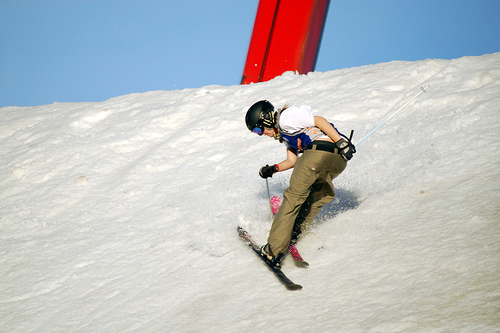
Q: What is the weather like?
A: It is clear.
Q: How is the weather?
A: It is clear.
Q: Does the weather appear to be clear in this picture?
A: Yes, it is clear.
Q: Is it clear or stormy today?
A: It is clear.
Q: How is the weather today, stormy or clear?
A: It is clear.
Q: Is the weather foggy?
A: No, it is clear.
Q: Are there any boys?
A: No, there are no boys.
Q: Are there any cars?
A: No, there are no cars.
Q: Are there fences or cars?
A: No, there are no cars or fences.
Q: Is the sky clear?
A: Yes, the sky is clear.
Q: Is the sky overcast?
A: No, the sky is clear.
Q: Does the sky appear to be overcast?
A: No, the sky is clear.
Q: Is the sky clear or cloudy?
A: The sky is clear.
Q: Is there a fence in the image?
A: No, there are no fences.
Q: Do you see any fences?
A: No, there are no fences.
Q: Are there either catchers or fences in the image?
A: No, there are no fences or catchers.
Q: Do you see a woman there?
A: No, there are no women.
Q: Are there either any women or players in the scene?
A: No, there are no women or players.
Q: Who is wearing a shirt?
A: The man is wearing a shirt.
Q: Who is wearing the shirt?
A: The man is wearing a shirt.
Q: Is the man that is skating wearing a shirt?
A: Yes, the man is wearing a shirt.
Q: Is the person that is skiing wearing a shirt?
A: Yes, the man is wearing a shirt.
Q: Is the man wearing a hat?
A: No, the man is wearing a shirt.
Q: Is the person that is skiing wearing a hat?
A: No, the man is wearing a shirt.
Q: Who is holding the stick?
A: The man is holding the stick.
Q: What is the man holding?
A: The man is holding the stick.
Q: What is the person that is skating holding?
A: The man is holding the stick.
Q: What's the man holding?
A: The man is holding the stick.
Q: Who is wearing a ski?
A: The man is wearing a ski.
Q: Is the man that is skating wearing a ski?
A: Yes, the man is wearing a ski.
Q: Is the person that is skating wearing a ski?
A: Yes, the man is wearing a ski.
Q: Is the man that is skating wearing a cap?
A: No, the man is wearing a ski.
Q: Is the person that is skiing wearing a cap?
A: No, the man is wearing a ski.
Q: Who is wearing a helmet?
A: The man is wearing a helmet.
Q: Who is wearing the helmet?
A: The man is wearing a helmet.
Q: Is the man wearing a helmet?
A: Yes, the man is wearing a helmet.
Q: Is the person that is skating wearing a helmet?
A: Yes, the man is wearing a helmet.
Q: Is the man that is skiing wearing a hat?
A: No, the man is wearing a helmet.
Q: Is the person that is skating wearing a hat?
A: No, the man is wearing a helmet.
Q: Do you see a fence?
A: No, there are no fences.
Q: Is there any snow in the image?
A: Yes, there is snow.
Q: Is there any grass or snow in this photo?
A: Yes, there is snow.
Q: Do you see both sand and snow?
A: No, there is snow but no sand.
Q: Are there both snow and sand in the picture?
A: No, there is snow but no sand.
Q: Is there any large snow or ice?
A: Yes, there is large snow.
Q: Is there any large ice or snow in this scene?
A: Yes, there is large snow.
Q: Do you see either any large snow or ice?
A: Yes, there is large snow.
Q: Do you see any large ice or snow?
A: Yes, there is large snow.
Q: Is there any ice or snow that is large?
A: Yes, the snow is large.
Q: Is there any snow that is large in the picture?
A: Yes, there is large snow.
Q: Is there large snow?
A: Yes, there is large snow.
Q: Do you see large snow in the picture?
A: Yes, there is large snow.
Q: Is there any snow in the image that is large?
A: Yes, there is snow that is large.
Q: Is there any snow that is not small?
A: Yes, there is large snow.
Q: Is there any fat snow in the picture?
A: Yes, there is fat snow.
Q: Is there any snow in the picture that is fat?
A: Yes, there is snow that is fat.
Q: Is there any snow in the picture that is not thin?
A: Yes, there is fat snow.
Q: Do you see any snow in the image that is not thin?
A: Yes, there is fat snow.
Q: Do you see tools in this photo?
A: No, there are no tools.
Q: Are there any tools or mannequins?
A: No, there are no tools or mannequins.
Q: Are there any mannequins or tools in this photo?
A: No, there are no tools or mannequins.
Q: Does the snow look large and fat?
A: Yes, the snow is large and fat.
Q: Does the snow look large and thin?
A: No, the snow is large but fat.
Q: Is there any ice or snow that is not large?
A: No, there is snow but it is large.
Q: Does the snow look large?
A: Yes, the snow is large.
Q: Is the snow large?
A: Yes, the snow is large.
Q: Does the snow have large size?
A: Yes, the snow is large.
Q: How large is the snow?
A: The snow is large.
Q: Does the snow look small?
A: No, the snow is large.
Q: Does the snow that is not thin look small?
A: No, the snow is large.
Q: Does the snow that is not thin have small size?
A: No, the snow is large.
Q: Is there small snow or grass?
A: No, there is snow but it is large.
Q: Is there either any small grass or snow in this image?
A: No, there is snow but it is large.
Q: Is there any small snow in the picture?
A: No, there is snow but it is large.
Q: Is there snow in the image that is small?
A: No, there is snow but it is large.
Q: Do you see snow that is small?
A: No, there is snow but it is large.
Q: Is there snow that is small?
A: No, there is snow but it is large.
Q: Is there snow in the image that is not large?
A: No, there is snow but it is large.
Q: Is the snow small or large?
A: The snow is large.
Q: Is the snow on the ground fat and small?
A: No, the snow is fat but large.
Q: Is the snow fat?
A: Yes, the snow is fat.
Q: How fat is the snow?
A: The snow is fat.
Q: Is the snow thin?
A: No, the snow is fat.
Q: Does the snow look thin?
A: No, the snow is fat.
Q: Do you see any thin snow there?
A: No, there is snow but it is fat.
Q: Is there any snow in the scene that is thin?
A: No, there is snow but it is fat.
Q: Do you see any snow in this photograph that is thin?
A: No, there is snow but it is fat.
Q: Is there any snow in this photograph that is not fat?
A: No, there is snow but it is fat.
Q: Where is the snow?
A: The snow is on the ground.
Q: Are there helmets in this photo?
A: Yes, there is a helmet.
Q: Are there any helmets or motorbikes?
A: Yes, there is a helmet.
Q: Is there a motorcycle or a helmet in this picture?
A: Yes, there is a helmet.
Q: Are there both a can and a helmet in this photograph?
A: No, there is a helmet but no cans.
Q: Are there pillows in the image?
A: No, there are no pillows.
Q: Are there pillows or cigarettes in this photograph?
A: No, there are no pillows or cigarettes.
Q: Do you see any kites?
A: No, there are no kites.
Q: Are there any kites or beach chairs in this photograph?
A: No, there are no kites or beach chairs.